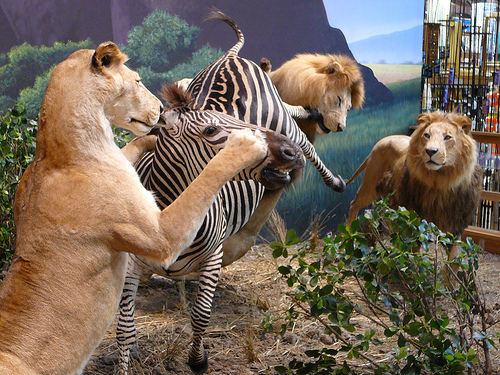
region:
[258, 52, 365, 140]
A lion biting into a zebra leg.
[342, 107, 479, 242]
A brown most visible lion.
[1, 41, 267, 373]
A brown lioness standing up.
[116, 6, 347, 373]
A black and white zebra.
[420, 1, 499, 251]
A tall bookcase.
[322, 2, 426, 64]
A blue sky.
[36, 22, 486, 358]
a wildlife exhibit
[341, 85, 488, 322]
a stuffed lion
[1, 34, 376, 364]
a female lion attacking a zebra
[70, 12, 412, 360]
a zebra being attacked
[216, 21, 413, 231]
a male lion biting a zebra foot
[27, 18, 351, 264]
a lion biting a zebra ear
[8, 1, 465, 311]
a picture back drop for an exhibit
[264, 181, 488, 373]
a fake green plant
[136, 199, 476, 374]
straw on the floor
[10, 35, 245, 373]
The lions paw is on the zebras face.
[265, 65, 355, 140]
The zebras leg is in the lions mouth.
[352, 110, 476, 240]
Another lion is standing there watching.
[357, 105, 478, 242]
The lion is brown.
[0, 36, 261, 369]
The lion is brown.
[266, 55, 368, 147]
The lion is brown.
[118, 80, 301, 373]
The zebra is black and white.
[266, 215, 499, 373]
The leaves on the bush are green.